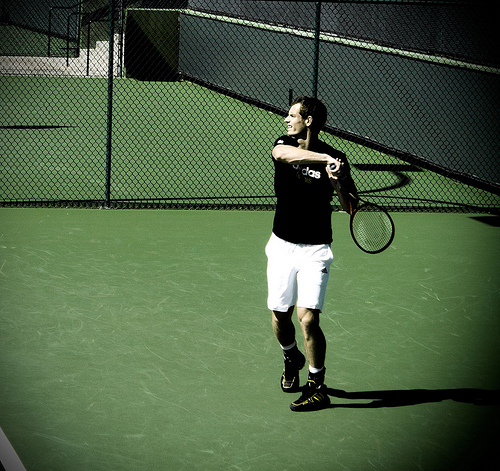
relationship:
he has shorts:
[254, 94, 359, 412] [262, 232, 337, 313]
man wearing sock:
[254, 94, 359, 412] [278, 341, 300, 357]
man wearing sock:
[254, 94, 359, 412] [307, 365, 327, 381]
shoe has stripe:
[292, 383, 335, 415] [311, 392, 321, 403]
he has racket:
[254, 94, 359, 412] [343, 189, 395, 256]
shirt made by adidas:
[271, 138, 352, 243] [289, 162, 326, 183]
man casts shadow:
[254, 94, 359, 412] [327, 379, 499, 416]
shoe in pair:
[292, 383, 335, 415] [278, 355, 332, 413]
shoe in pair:
[274, 352, 305, 394] [278, 355, 332, 413]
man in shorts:
[254, 94, 359, 412] [262, 232, 337, 313]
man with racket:
[254, 94, 359, 412] [343, 189, 395, 256]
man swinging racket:
[254, 94, 359, 412] [343, 189, 395, 256]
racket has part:
[343, 189, 395, 256] [343, 189, 367, 212]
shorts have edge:
[262, 232, 337, 313] [267, 301, 294, 315]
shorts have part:
[262, 232, 337, 313] [265, 262, 294, 312]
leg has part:
[295, 268, 330, 380] [299, 314, 316, 332]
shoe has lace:
[292, 383, 335, 415] [302, 381, 315, 398]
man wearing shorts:
[254, 94, 359, 412] [262, 232, 337, 313]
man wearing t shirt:
[254, 94, 359, 412] [271, 138, 352, 243]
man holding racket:
[254, 94, 359, 412] [343, 189, 395, 256]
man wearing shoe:
[254, 94, 359, 412] [292, 383, 335, 415]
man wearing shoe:
[254, 94, 359, 412] [274, 352, 305, 394]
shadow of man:
[327, 379, 499, 416] [254, 94, 359, 412]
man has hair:
[254, 94, 359, 412] [290, 94, 327, 131]